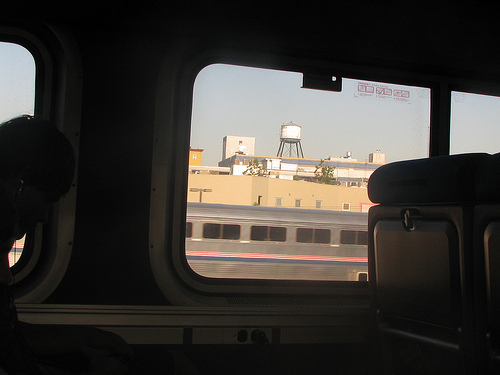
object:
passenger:
[0, 110, 132, 367]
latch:
[401, 207, 419, 231]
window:
[184, 61, 432, 283]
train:
[0, 0, 500, 375]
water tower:
[276, 118, 306, 158]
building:
[217, 128, 391, 213]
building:
[187, 146, 206, 173]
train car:
[185, 200, 369, 279]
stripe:
[185, 252, 283, 259]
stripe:
[273, 263, 325, 266]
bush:
[312, 158, 341, 185]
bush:
[244, 156, 270, 177]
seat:
[365, 152, 500, 333]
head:
[0, 114, 79, 254]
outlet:
[223, 327, 275, 345]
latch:
[299, 72, 343, 93]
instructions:
[352, 79, 414, 103]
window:
[185, 222, 194, 239]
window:
[201, 222, 222, 239]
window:
[222, 223, 241, 241]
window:
[249, 224, 268, 241]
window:
[270, 225, 288, 243]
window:
[295, 227, 314, 244]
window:
[315, 228, 333, 244]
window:
[339, 229, 358, 245]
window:
[356, 230, 371, 245]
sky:
[190, 61, 500, 166]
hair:
[0, 110, 78, 242]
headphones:
[14, 174, 34, 204]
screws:
[150, 244, 154, 249]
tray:
[372, 207, 463, 334]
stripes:
[264, 256, 270, 257]